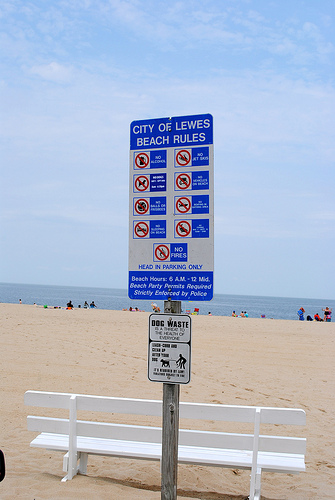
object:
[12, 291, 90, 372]
train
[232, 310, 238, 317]
people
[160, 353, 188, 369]
icon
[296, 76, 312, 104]
ground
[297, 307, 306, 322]
people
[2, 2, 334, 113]
blue sky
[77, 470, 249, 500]
shadow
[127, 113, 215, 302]
post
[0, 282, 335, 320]
ocean water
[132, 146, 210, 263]
circles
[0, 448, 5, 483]
trashcan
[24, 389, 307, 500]
bench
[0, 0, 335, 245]
clouds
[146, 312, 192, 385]
post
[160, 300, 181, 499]
pole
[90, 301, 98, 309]
people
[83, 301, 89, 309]
people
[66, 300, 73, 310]
people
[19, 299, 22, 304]
people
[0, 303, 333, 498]
beach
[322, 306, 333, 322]
people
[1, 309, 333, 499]
land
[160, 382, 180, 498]
bar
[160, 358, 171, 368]
dog